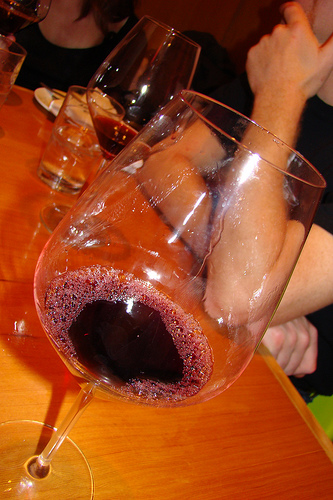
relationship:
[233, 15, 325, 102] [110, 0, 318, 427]
hand of person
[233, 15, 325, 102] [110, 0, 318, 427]
hand of man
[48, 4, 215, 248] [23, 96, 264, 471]
wineglass on table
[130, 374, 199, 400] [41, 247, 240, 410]
bubbles on wine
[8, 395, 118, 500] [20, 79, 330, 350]
base of glass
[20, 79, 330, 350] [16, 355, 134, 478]
glass has stem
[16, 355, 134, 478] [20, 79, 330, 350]
stem of glass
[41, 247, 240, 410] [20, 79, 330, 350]
wine in glass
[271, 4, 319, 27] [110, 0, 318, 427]
finger of person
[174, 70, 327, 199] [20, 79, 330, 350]
mouth of glass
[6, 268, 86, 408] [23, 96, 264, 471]
shadow on table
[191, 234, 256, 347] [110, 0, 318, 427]
elbow of person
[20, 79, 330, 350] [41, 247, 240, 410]
glass of wine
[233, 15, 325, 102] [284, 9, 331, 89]
hand touching face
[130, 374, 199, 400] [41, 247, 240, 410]
bubbles in wine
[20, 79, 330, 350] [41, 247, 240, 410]
glass with wine